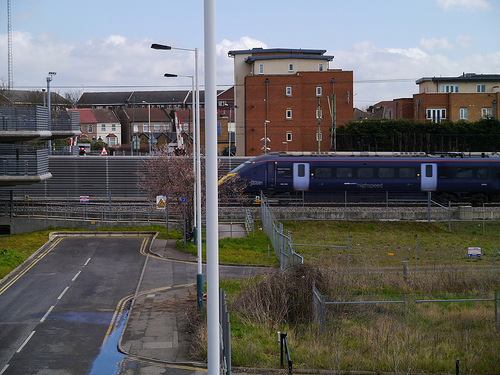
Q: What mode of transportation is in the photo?
A: A train.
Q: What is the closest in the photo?
A: A white pole.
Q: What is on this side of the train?
A: A grassy field.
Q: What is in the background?
A: Buildings.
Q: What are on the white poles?
A: Street poles.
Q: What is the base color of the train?
A: Purple.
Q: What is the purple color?
A: Train.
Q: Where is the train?
A: On tracks.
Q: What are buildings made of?
A: Brick.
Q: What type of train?
A: Passenger.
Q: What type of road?
A: Dead end.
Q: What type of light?
A: Street.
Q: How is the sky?
A: Cloudy.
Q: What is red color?
A: Building.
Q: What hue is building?
A: Red.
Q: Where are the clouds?
A: In the sky.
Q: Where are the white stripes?
A: On the road.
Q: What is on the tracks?
A: Train.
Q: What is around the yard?
A: Fenced.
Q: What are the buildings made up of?
A: Apartments.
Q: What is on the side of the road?
A: Water.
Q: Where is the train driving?
A: On the tracks.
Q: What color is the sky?
A: Blue.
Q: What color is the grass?
A: Green.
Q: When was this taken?
A: Daytime.